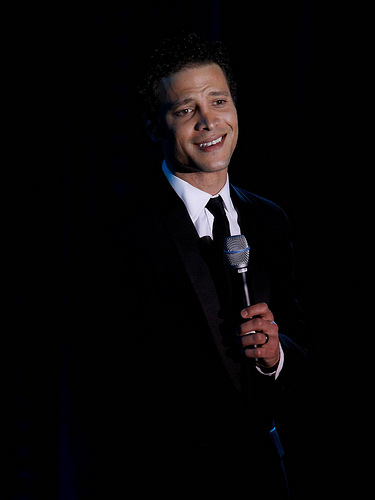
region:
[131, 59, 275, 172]
the head of a man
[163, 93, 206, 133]
the eye of a man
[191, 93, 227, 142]
the nose of a man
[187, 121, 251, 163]
the mouth of a man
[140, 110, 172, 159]
the ear of a man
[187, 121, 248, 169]
the teeth of a man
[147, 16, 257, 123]
the hair of a man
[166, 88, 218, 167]
the cheek of a man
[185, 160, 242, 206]
the chin of a man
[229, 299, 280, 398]
the fingers of a man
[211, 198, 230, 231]
this is a tie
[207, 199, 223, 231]
the tie is black in color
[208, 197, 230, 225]
the tie is long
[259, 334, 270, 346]
this is a ring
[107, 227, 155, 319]
this is a coat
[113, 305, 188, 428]
the coat is black in color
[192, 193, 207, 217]
this is a shirt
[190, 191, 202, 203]
the shirt is white in color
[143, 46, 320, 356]
this is a man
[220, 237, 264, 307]
this is a microphone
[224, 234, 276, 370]
The man is holding a microphone in his left hand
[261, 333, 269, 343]
A ring on the man's finger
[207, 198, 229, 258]
The man is wearing a tie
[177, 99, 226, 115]
The eyes of the man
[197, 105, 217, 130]
The nose of the man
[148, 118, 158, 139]
The right ear of the man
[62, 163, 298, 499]
The man is wearing a suit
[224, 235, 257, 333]
The microphone is small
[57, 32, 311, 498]
A man is holding a microphone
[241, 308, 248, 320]
A fingernail on the finger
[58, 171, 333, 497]
the man is in a suit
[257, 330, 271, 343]
ring is on the finger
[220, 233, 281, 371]
the hand holds a microphone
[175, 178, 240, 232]
the shirt is white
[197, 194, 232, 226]
the tie is black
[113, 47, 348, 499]
the man is smiling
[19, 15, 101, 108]
the background is black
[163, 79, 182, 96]
vein is on the forehead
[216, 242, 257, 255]
blue strip is on the mic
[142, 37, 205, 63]
the hair is curled